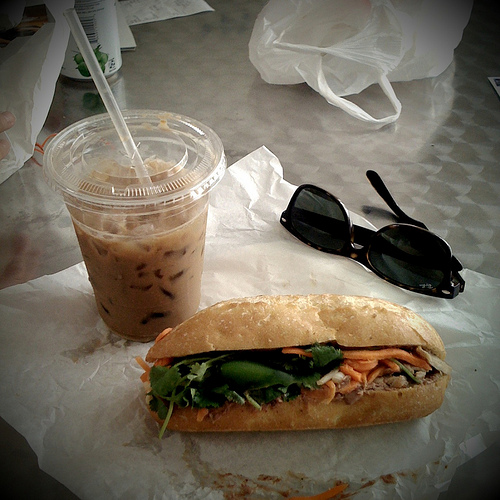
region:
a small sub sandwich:
[130, 285, 446, 436]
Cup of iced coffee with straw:
[36, 100, 216, 345]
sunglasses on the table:
[270, 145, 456, 295]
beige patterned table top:
[0, 0, 495, 265]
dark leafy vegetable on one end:
[150, 357, 280, 409]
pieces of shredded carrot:
[295, 346, 425, 387]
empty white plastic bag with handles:
[252, 0, 477, 126]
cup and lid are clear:
[47, 106, 227, 332]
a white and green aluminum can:
[17, 1, 120, 86]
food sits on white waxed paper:
[1, 146, 498, 498]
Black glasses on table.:
[289, 170, 473, 297]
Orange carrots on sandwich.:
[313, 345, 429, 383]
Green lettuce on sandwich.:
[156, 353, 308, 405]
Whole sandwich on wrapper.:
[130, 292, 450, 425]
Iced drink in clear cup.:
[40, 108, 230, 339]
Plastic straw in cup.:
[60, 33, 156, 184]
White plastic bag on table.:
[247, 0, 475, 128]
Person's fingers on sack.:
[0, 98, 15, 168]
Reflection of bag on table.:
[250, 58, 465, 168]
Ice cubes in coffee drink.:
[82, 211, 191, 312]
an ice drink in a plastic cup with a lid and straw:
[45, 28, 207, 343]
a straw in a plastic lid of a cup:
[36, 10, 236, 222]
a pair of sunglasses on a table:
[283, 160, 474, 295]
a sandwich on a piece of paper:
[139, 283, 445, 451]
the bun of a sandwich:
[139, 289, 453, 361]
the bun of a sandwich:
[137, 376, 455, 442]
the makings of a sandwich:
[143, 337, 457, 406]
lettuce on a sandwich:
[150, 357, 292, 405]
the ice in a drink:
[126, 253, 181, 303]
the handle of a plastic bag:
[300, 59, 408, 131]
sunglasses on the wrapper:
[287, 152, 496, 277]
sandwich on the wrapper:
[162, 291, 467, 435]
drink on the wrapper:
[51, 88, 260, 306]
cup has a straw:
[82, 18, 180, 169]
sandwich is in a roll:
[131, 299, 484, 437]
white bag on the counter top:
[221, 0, 471, 103]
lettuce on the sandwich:
[146, 361, 295, 402]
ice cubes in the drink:
[73, 227, 199, 332]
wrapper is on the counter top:
[242, 117, 495, 371]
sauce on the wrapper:
[175, 439, 452, 499]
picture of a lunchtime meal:
[31, 74, 485, 486]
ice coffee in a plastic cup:
[42, 93, 216, 336]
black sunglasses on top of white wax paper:
[257, 145, 472, 293]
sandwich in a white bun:
[137, 283, 455, 440]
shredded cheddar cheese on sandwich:
[314, 337, 433, 397]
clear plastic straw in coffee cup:
[90, 85, 178, 205]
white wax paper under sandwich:
[40, 187, 493, 481]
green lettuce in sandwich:
[150, 329, 335, 424]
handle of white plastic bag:
[286, 86, 417, 125]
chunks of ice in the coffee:
[97, 250, 182, 317]